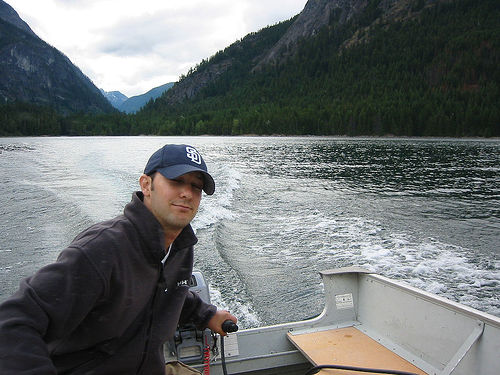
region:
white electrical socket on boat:
[332, 292, 362, 310]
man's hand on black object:
[220, 317, 245, 338]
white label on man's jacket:
[170, 272, 203, 298]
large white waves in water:
[346, 235, 427, 264]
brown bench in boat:
[295, 332, 375, 373]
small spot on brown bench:
[336, 325, 357, 340]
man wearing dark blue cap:
[135, 140, 240, 190]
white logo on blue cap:
[176, 145, 216, 165]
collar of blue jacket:
[122, 188, 229, 264]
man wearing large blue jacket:
[55, 177, 280, 359]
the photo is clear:
[3, 3, 496, 373]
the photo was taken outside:
[4, 2, 489, 371]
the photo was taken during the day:
[5, 5, 494, 373]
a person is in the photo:
[5, 119, 230, 374]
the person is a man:
[7, 127, 229, 373]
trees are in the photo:
[12, 5, 492, 132]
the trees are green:
[210, 51, 499, 138]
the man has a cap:
[129, 143, 271, 208]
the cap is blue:
[128, 142, 272, 207]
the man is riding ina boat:
[0, 123, 499, 372]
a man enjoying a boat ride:
[10, 6, 475, 356]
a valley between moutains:
[51, 4, 231, 113]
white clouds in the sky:
[112, 16, 182, 66]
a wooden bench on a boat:
[304, 336, 394, 373]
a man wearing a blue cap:
[14, 133, 236, 364]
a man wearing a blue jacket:
[15, 143, 221, 370]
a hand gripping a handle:
[208, 296, 247, 338]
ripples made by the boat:
[252, 184, 287, 282]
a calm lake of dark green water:
[340, 144, 455, 213]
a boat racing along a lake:
[276, 269, 493, 372]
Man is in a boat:
[0, 124, 253, 374]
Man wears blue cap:
[5, 121, 249, 373]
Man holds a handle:
[5, 126, 251, 373]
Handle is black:
[221, 318, 243, 336]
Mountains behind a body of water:
[6, 1, 496, 137]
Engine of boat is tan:
[187, 264, 217, 304]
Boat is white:
[208, 256, 492, 373]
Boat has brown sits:
[283, 326, 451, 372]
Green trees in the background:
[3, 52, 487, 144]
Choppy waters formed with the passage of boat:
[200, 170, 475, 327]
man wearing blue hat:
[2, 139, 233, 373]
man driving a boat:
[5, 137, 241, 372]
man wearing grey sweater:
[0, 138, 240, 373]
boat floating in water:
[159, 263, 497, 372]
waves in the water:
[2, 153, 263, 354]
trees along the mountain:
[5, 20, 493, 143]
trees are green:
[0, 12, 496, 137]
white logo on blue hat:
[180, 140, 202, 170]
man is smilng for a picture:
[0, 135, 240, 368]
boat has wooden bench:
[118, 265, 497, 374]